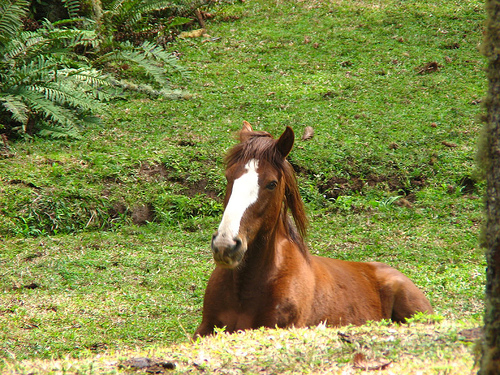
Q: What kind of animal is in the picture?
A: A horse.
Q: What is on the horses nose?
A: A white stripe.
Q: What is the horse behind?
A: A hill.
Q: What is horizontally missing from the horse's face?
A: An eye.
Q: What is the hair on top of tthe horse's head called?
A: A mane.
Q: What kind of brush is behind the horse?
A: Ferns.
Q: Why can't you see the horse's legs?
A: The horse is laying down.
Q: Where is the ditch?
A: Behind horse.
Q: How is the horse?
A: Laying.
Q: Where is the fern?
A: Field.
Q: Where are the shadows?
A: Ground.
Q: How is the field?
A: Grassy.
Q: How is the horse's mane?
A: Brown.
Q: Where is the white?
A: Face.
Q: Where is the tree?
A: On right.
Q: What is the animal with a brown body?
A: A horse.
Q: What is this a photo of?
A: A horse.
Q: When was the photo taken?
A: During the day.